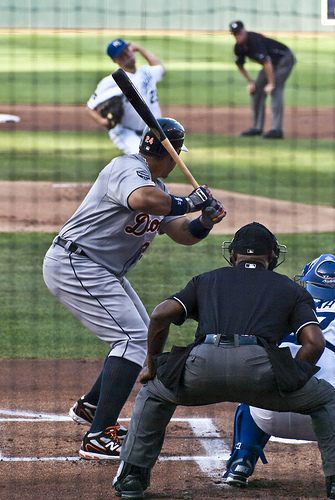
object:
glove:
[101, 96, 124, 130]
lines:
[0, 410, 234, 462]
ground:
[0, 0, 333, 500]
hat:
[229, 222, 278, 257]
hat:
[230, 20, 244, 34]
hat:
[105, 37, 128, 59]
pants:
[119, 334, 335, 475]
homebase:
[49, 110, 333, 391]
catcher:
[220, 253, 335, 485]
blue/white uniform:
[248, 297, 333, 441]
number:
[145, 133, 154, 144]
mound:
[225, 189, 293, 221]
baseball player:
[86, 37, 166, 157]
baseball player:
[42, 118, 224, 459]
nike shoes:
[67, 395, 127, 460]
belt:
[123, 125, 143, 136]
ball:
[126, 42, 134, 51]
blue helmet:
[139, 118, 188, 156]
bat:
[111, 68, 217, 221]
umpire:
[229, 17, 295, 138]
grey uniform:
[43, 154, 187, 368]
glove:
[185, 184, 212, 214]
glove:
[201, 196, 226, 225]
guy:
[112, 224, 335, 500]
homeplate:
[263, 428, 319, 448]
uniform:
[87, 65, 165, 154]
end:
[112, 69, 121, 83]